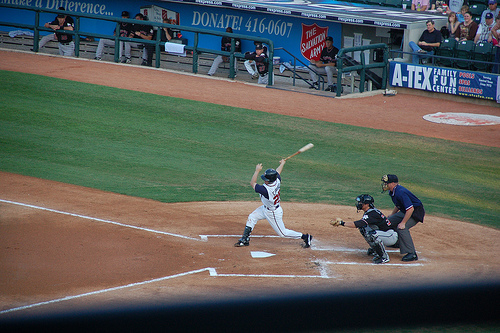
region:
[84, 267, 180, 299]
chalk base line on the field.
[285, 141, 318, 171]
bat in the player's hand.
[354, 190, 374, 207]
mask on catcher's head.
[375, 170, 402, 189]
mask on umpire's head.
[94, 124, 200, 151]
grass in foul territory.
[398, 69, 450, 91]
advertisement on the backstop.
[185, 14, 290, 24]
advertisement in the dugout.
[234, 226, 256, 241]
shin protector on batter's leg.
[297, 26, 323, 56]
red logo on dugout wall.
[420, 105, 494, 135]
design in the dirt.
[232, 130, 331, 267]
the man swinging a bat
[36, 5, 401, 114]
players in the dugout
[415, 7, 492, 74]
spectators in the stands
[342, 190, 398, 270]
the catcher behind the man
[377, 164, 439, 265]
the umpire behind the catcher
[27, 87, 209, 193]
the grass is green and cut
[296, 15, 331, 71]
the red and white salvation army sign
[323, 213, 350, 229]
the mitt on the catcher's hand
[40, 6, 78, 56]
a man leaning on the dugout fence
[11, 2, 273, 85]
the fence is green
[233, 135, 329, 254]
baseball player swinging at ball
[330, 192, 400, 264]
catcher squatting behind swinger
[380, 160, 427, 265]
umpire squatting behind catcher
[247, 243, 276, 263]
white home plate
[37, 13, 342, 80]
players sitting in dugout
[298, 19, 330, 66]
red and white salvation army logo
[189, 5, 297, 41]
banner with phone number asking for donation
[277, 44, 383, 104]
staircase leading to dugout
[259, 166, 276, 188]
black batter's helmet on players head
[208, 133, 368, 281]
a swing by the baseball batter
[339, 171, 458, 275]
the umpire and the catcher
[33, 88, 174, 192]
the grass in foul territory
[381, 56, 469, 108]
A-tex advertisement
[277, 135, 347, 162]
the bat that was swining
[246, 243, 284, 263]
home plate that is white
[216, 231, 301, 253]
the batter box for the batter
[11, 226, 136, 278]
the beginning of the infield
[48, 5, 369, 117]
the dug out of the team in the field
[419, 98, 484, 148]
where the on deck circle is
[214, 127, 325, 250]
A baseball player swings his bat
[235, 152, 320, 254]
A man in a white and blue uniform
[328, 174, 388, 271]
A catcher crouching with his arm extended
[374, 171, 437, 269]
An umpire crouching wearing gray pants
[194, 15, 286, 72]
Players sitting on a bench in front of a blue wall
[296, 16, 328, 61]
Red Salvation Army Logo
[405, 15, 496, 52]
People sitting in green chairs watching the game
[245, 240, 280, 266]
Home plate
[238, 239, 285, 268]
A white shape in the dirt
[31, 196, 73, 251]
A white line in brown dirt